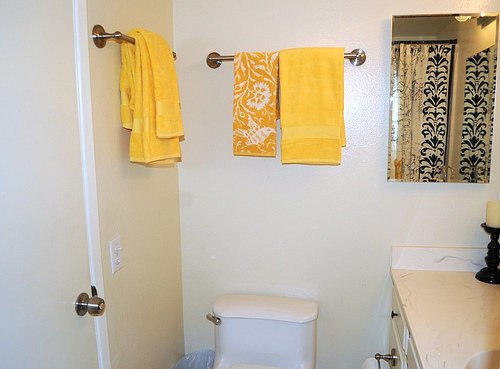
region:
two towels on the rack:
[204, 40, 375, 179]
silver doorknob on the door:
[74, 283, 106, 322]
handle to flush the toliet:
[202, 307, 224, 329]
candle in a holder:
[474, 193, 499, 294]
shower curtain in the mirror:
[397, 36, 451, 179]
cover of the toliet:
[201, 286, 320, 323]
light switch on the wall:
[102, 235, 132, 278]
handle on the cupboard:
[367, 345, 390, 366]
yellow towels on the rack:
[86, 15, 188, 180]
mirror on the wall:
[383, 15, 498, 182]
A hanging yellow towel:
[278, 45, 349, 165]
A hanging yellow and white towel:
[230, 47, 276, 158]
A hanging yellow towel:
[117, 25, 183, 170]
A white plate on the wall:
[108, 234, 125, 274]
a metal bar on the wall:
[201, 47, 366, 69]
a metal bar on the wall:
[91, 19, 176, 62]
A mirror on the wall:
[386, 13, 499, 186]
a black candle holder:
[476, 223, 499, 283]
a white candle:
[486, 198, 498, 225]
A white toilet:
[202, 293, 324, 368]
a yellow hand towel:
[111, 23, 191, 167]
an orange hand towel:
[230, 36, 283, 162]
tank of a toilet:
[198, 275, 333, 365]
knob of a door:
[70, 283, 108, 316]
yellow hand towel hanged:
[279, 32, 358, 169]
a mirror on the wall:
[382, 11, 496, 184]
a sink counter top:
[375, 234, 497, 359]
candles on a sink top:
[472, 198, 497, 235]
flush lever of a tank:
[195, 305, 227, 328]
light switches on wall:
[102, 236, 132, 276]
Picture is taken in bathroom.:
[33, 18, 463, 353]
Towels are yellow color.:
[112, 45, 340, 166]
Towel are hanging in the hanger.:
[89, 16, 364, 166]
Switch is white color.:
[104, 233, 126, 281]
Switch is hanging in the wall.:
[102, 220, 134, 279]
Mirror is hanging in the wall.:
[382, 7, 499, 189]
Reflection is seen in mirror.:
[390, 13, 495, 184]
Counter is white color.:
[396, 250, 499, 366]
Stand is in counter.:
[480, 220, 499, 292]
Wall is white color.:
[125, 20, 319, 265]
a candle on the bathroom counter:
[474, 197, 499, 287]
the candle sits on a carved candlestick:
[471, 197, 498, 284]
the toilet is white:
[203, 289, 325, 366]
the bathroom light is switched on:
[105, 230, 128, 278]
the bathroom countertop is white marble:
[386, 238, 496, 366]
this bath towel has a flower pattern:
[227, 41, 281, 162]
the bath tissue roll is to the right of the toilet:
[357, 345, 399, 366]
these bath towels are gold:
[113, 22, 188, 172]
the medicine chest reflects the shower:
[382, 6, 497, 188]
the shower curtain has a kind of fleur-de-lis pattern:
[383, 38, 457, 185]